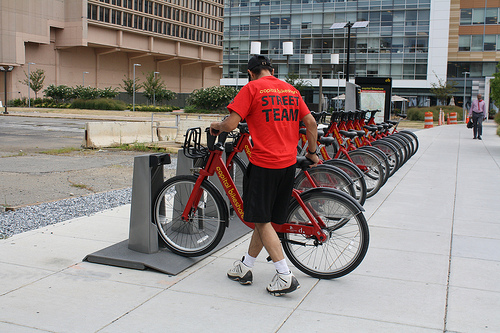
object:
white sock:
[242, 252, 257, 271]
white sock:
[273, 257, 290, 273]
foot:
[266, 274, 301, 296]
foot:
[227, 259, 254, 284]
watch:
[308, 149, 316, 154]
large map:
[361, 89, 386, 123]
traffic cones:
[424, 111, 457, 129]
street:
[318, 127, 497, 272]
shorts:
[243, 161, 296, 225]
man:
[209, 55, 320, 297]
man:
[466, 92, 485, 141]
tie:
[478, 99, 481, 111]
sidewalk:
[16, 119, 498, 330]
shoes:
[266, 273, 302, 296]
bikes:
[127, 105, 427, 284]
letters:
[216, 167, 245, 220]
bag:
[467, 120, 474, 129]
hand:
[469, 114, 472, 117]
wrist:
[304, 144, 323, 169]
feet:
[226, 256, 301, 297]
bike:
[151, 121, 370, 281]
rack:
[81, 148, 218, 276]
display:
[360, 89, 386, 124]